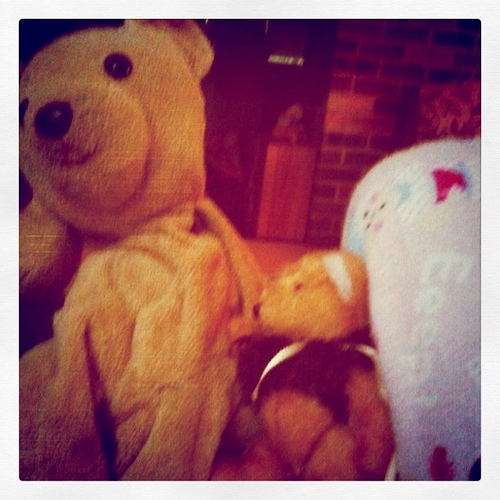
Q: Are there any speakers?
A: Yes, there is a speaker.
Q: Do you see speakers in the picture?
A: Yes, there is a speaker.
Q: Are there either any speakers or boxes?
A: Yes, there is a speaker.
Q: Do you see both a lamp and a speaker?
A: No, there is a speaker but no lamps.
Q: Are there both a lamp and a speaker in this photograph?
A: No, there is a speaker but no lamps.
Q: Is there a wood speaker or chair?
A: Yes, there is a wood speaker.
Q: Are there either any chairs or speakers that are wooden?
A: Yes, the speaker is wooden.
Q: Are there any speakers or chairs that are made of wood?
A: Yes, the speaker is made of wood.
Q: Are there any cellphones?
A: No, there are no cellphones.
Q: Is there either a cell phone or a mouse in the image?
A: No, there are no cell phones or computer mice.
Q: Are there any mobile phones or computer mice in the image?
A: No, there are no mobile phones or computer mice.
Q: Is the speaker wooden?
A: Yes, the speaker is wooden.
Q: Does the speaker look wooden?
A: Yes, the speaker is wooden.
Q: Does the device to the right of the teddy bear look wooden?
A: Yes, the speaker is wooden.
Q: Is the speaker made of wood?
A: Yes, the speaker is made of wood.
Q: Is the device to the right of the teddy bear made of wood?
A: Yes, the speaker is made of wood.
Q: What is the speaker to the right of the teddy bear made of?
A: The speaker is made of wood.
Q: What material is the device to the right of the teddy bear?
A: The speaker is made of wood.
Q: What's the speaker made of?
A: The speaker is made of wood.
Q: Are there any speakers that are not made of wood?
A: No, there is a speaker but it is made of wood.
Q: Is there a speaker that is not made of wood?
A: No, there is a speaker but it is made of wood.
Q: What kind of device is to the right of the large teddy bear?
A: The device is a speaker.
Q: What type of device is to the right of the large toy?
A: The device is a speaker.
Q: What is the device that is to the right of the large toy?
A: The device is a speaker.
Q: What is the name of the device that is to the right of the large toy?
A: The device is a speaker.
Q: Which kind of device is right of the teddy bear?
A: The device is a speaker.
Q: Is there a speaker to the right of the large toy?
A: Yes, there is a speaker to the right of the teddy bear.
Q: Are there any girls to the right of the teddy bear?
A: No, there is a speaker to the right of the teddy bear.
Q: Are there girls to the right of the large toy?
A: No, there is a speaker to the right of the teddy bear.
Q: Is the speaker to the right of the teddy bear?
A: Yes, the speaker is to the right of the teddy bear.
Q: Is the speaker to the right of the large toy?
A: Yes, the speaker is to the right of the teddy bear.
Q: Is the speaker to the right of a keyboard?
A: No, the speaker is to the right of the teddy bear.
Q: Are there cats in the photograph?
A: No, there are no cats.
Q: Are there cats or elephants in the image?
A: No, there are no cats or elephants.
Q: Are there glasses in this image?
A: No, there are no glasses.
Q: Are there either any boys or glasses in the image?
A: No, there are no glasses or boys.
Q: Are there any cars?
A: No, there are no cars.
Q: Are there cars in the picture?
A: No, there are no cars.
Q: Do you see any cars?
A: No, there are no cars.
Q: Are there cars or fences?
A: No, there are no cars or fences.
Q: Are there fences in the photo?
A: No, there are no fences.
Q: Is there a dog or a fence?
A: No, there are no fences or dogs.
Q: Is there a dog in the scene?
A: No, there are no dogs.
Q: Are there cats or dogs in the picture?
A: No, there are no dogs or cats.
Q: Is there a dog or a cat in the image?
A: No, there are no dogs or cats.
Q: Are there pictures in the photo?
A: No, there are no pictures.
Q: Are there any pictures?
A: No, there are no pictures.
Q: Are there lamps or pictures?
A: No, there are no pictures or lamps.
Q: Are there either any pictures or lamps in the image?
A: No, there are no pictures or lamps.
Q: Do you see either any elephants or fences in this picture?
A: No, there are no fences or elephants.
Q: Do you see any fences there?
A: No, there are no fences.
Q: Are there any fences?
A: No, there are no fences.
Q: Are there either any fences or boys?
A: No, there are no fences or boys.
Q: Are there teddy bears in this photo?
A: Yes, there is a teddy bear.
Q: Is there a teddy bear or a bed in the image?
A: Yes, there is a teddy bear.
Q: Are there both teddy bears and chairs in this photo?
A: No, there is a teddy bear but no chairs.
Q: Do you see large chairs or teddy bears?
A: Yes, there is a large teddy bear.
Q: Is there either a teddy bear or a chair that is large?
A: Yes, the teddy bear is large.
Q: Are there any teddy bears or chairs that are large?
A: Yes, the teddy bear is large.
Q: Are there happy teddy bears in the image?
A: Yes, there is a happy teddy bear.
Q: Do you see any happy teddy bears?
A: Yes, there is a happy teddy bear.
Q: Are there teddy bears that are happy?
A: Yes, there is a teddy bear that is happy.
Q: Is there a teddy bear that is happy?
A: Yes, there is a teddy bear that is happy.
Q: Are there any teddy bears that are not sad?
A: Yes, there is a happy teddy bear.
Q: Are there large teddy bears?
A: Yes, there is a large teddy bear.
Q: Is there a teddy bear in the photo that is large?
A: Yes, there is a teddy bear that is large.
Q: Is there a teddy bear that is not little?
A: Yes, there is a large teddy bear.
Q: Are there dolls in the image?
A: No, there are no dolls.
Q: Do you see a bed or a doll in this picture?
A: No, there are no dolls or beds.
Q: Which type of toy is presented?
A: The toy is a teddy bear.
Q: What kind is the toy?
A: The toy is a teddy bear.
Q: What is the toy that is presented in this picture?
A: The toy is a teddy bear.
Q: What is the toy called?
A: The toy is a teddy bear.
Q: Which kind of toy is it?
A: The toy is a teddy bear.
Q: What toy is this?
A: This is a teddy bear.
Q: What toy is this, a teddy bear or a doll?
A: This is a teddy bear.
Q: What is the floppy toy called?
A: The toy is a teddy bear.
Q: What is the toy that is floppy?
A: The toy is a teddy bear.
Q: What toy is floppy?
A: The toy is a teddy bear.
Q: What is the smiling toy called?
A: The toy is a teddy bear.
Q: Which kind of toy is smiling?
A: The toy is a teddy bear.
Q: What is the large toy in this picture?
A: The toy is a teddy bear.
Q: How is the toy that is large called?
A: The toy is a teddy bear.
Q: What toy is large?
A: The toy is a teddy bear.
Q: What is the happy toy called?
A: The toy is a teddy bear.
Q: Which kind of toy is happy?
A: The toy is a teddy bear.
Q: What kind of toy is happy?
A: The toy is a teddy bear.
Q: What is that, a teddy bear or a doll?
A: That is a teddy bear.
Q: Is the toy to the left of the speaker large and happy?
A: Yes, the teddy bear is large and happy.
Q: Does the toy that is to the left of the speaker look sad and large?
A: No, the teddy bear is large but happy.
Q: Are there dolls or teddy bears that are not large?
A: No, there is a teddy bear but it is large.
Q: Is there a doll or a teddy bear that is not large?
A: No, there is a teddy bear but it is large.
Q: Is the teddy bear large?
A: Yes, the teddy bear is large.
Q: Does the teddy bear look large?
A: Yes, the teddy bear is large.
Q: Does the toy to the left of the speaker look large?
A: Yes, the teddy bear is large.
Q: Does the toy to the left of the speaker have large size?
A: Yes, the teddy bear is large.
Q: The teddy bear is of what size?
A: The teddy bear is large.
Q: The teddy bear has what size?
A: The teddy bear is large.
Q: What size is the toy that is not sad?
A: The teddy bear is large.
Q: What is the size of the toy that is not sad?
A: The teddy bear is large.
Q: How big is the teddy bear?
A: The teddy bear is large.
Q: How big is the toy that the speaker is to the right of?
A: The teddy bear is large.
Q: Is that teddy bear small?
A: No, the teddy bear is large.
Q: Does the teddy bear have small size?
A: No, the teddy bear is large.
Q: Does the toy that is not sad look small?
A: No, the teddy bear is large.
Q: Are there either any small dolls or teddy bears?
A: No, there is a teddy bear but it is large.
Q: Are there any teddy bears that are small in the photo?
A: No, there is a teddy bear but it is large.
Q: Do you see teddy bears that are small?
A: No, there is a teddy bear but it is large.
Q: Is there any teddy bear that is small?
A: No, there is a teddy bear but it is large.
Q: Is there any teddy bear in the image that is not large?
A: No, there is a teddy bear but it is large.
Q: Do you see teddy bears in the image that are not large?
A: No, there is a teddy bear but it is large.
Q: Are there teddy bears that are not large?
A: No, there is a teddy bear but it is large.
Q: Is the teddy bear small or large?
A: The teddy bear is large.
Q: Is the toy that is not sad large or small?
A: The teddy bear is large.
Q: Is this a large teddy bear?
A: Yes, this is a large teddy bear.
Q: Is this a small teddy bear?
A: No, this is a large teddy bear.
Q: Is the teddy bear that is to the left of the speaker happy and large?
A: Yes, the teddy bear is happy and large.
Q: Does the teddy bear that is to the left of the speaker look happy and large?
A: Yes, the teddy bear is happy and large.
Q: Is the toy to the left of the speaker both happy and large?
A: Yes, the teddy bear is happy and large.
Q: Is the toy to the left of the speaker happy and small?
A: No, the teddy bear is happy but large.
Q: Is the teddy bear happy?
A: Yes, the teddy bear is happy.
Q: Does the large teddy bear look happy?
A: Yes, the teddy bear is happy.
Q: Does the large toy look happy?
A: Yes, the teddy bear is happy.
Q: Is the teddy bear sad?
A: No, the teddy bear is happy.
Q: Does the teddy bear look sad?
A: No, the teddy bear is happy.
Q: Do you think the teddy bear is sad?
A: No, the teddy bear is happy.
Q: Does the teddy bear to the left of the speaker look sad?
A: No, the teddy bear is happy.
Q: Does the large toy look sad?
A: No, the teddy bear is happy.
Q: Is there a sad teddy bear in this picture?
A: No, there is a teddy bear but it is happy.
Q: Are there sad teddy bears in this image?
A: No, there is a teddy bear but it is happy.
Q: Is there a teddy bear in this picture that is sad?
A: No, there is a teddy bear but it is happy.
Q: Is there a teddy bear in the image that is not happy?
A: No, there is a teddy bear but it is happy.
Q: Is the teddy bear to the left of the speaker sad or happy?
A: The teddy bear is happy.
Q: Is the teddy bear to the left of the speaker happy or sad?
A: The teddy bear is happy.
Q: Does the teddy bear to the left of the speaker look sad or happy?
A: The teddy bear is happy.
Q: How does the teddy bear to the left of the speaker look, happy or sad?
A: The teddy bear is happy.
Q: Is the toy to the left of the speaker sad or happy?
A: The teddy bear is happy.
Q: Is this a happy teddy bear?
A: Yes, this is a happy teddy bear.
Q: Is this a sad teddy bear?
A: No, this is a happy teddy bear.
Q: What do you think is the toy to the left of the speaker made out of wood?
A: The toy is a teddy bear.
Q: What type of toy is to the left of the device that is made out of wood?
A: The toy is a teddy bear.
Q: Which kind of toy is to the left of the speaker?
A: The toy is a teddy bear.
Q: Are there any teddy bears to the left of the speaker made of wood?
A: Yes, there is a teddy bear to the left of the speaker.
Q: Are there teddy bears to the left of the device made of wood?
A: Yes, there is a teddy bear to the left of the speaker.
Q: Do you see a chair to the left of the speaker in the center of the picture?
A: No, there is a teddy bear to the left of the speaker.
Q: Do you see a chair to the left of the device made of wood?
A: No, there is a teddy bear to the left of the speaker.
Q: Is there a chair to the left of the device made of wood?
A: No, there is a teddy bear to the left of the speaker.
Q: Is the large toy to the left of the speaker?
A: Yes, the teddy bear is to the left of the speaker.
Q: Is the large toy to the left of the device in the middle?
A: Yes, the teddy bear is to the left of the speaker.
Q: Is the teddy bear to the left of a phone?
A: No, the teddy bear is to the left of the speaker.